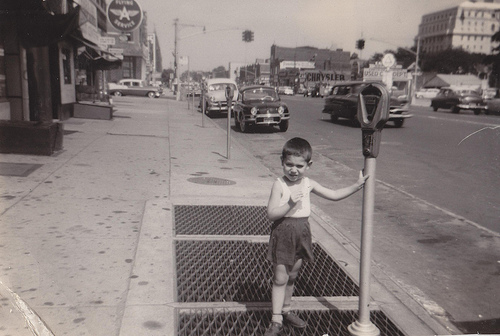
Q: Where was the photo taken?
A: It was taken at the sidewalk.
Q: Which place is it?
A: It is a sidewalk.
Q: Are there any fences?
A: No, there are no fences.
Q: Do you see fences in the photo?
A: No, there are no fences.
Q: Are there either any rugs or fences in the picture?
A: No, there are no fences or rugs.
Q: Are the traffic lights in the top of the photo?
A: Yes, the traffic lights are in the top of the image.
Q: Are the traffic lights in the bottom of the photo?
A: No, the traffic lights are in the top of the image.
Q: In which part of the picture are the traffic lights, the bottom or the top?
A: The traffic lights are in the top of the image.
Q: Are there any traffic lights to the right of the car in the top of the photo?
A: Yes, there are traffic lights to the right of the car.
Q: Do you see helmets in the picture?
A: No, there are no helmets.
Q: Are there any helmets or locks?
A: No, there are no helmets or locks.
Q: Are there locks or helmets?
A: No, there are no helmets or locks.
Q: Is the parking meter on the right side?
A: Yes, the parking meter is on the right of the image.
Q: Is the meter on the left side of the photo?
A: No, the meter is on the right of the image.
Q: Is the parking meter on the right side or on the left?
A: The parking meter is on the right of the image.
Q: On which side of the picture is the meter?
A: The meter is on the right of the image.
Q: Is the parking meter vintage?
A: Yes, the parking meter is vintage.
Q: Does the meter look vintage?
A: Yes, the meter is vintage.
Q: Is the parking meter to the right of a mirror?
A: No, the parking meter is to the right of the car.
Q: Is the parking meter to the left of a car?
A: No, the parking meter is to the right of a car.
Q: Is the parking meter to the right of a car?
A: Yes, the parking meter is to the right of a car.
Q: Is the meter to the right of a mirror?
A: No, the meter is to the right of a car.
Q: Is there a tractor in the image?
A: No, there are no tractors.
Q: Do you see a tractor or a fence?
A: No, there are no tractors or fences.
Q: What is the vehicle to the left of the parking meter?
A: The vehicle is a car.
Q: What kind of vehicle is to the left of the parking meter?
A: The vehicle is a car.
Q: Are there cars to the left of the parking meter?
A: Yes, there is a car to the left of the parking meter.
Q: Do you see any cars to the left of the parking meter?
A: Yes, there is a car to the left of the parking meter.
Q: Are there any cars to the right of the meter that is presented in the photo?
A: No, the car is to the left of the meter.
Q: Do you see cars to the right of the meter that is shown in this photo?
A: No, the car is to the left of the meter.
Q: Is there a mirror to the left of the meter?
A: No, there is a car to the left of the meter.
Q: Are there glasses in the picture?
A: No, there are no glasses.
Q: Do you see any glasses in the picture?
A: No, there are no glasses.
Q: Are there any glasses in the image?
A: No, there are no glasses.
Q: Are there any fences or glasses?
A: No, there are no glasses or fences.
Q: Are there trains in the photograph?
A: No, there are no trains.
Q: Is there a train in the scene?
A: No, there are no trains.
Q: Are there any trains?
A: No, there are no trains.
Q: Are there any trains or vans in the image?
A: No, there are no trains or vans.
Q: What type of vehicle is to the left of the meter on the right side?
A: The vehicle is a car.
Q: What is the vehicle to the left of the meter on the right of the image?
A: The vehicle is a car.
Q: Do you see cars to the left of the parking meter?
A: Yes, there is a car to the left of the parking meter.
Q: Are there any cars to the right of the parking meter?
A: No, the car is to the left of the parking meter.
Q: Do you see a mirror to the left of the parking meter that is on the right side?
A: No, there is a car to the left of the parking meter.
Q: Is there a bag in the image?
A: No, there are no bags.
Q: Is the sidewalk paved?
A: Yes, the sidewalk is paved.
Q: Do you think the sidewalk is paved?
A: Yes, the sidewalk is paved.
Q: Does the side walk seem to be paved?
A: Yes, the side walk is paved.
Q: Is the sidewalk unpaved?
A: No, the sidewalk is paved.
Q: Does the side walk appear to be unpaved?
A: No, the side walk is paved.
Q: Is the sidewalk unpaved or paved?
A: The sidewalk is paved.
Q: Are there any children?
A: Yes, there is a child.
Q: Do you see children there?
A: Yes, there is a child.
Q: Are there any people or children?
A: Yes, there is a child.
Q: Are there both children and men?
A: No, there is a child but no men.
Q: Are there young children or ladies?
A: Yes, there is a young child.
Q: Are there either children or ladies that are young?
A: Yes, the child is young.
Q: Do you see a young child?
A: Yes, there is a young child.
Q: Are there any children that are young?
A: Yes, there is a child that is young.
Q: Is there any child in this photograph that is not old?
A: Yes, there is an young child.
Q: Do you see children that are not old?
A: Yes, there is an young child.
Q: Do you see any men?
A: No, there are no men.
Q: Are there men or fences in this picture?
A: No, there are no men or fences.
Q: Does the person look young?
A: Yes, the child is young.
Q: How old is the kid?
A: The kid is young.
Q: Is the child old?
A: No, the child is young.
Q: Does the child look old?
A: No, the child is young.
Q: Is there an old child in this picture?
A: No, there is a child but he is young.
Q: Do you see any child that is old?
A: No, there is a child but he is young.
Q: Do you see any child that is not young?
A: No, there is a child but he is young.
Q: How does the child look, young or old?
A: The child is young.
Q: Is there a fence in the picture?
A: No, there are no fences.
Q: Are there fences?
A: No, there are no fences.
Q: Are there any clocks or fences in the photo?
A: No, there are no fences or clocks.